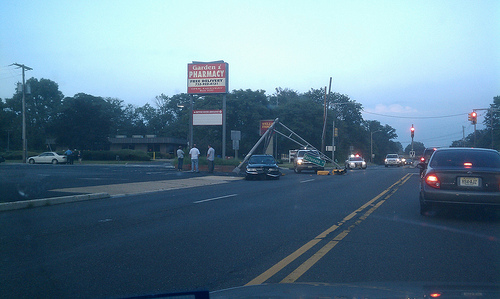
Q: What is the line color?
A: Yellow.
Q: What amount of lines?
A: Two.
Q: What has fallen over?
A: The street sign.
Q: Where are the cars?
A: On the street.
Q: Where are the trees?
A: Behind the buildings.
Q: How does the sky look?
A: Blue and clear.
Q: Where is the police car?
A: On the side of the street?.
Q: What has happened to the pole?
A: It fell down.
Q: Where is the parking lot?
A: In front of the building.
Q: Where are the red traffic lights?
A: Above the street.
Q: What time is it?
A: Daytime.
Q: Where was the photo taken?
A: On the street.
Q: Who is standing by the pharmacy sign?
A: Three men.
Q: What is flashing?
A: Police lights.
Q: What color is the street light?
A: Red.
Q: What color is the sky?
A: Blue.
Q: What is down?
A: A light pole.